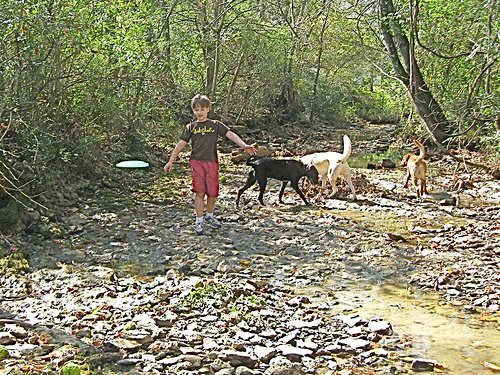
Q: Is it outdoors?
A: Yes, it is outdoors.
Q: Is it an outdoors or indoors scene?
A: It is outdoors.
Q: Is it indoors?
A: No, it is outdoors.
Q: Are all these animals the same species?
A: Yes, all the animals are dogs.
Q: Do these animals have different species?
A: No, all the animals are dogs.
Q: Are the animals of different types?
A: No, all the animals are dogs.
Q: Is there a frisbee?
A: Yes, there is a frisbee.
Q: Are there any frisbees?
A: Yes, there is a frisbee.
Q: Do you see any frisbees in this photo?
A: Yes, there is a frisbee.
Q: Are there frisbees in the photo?
A: Yes, there is a frisbee.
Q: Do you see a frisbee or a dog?
A: Yes, there is a frisbee.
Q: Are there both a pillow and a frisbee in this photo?
A: No, there is a frisbee but no pillows.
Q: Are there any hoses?
A: No, there are no hoses.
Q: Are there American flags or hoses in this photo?
A: No, there are no hoses or American flags.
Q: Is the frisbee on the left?
A: Yes, the frisbee is on the left of the image.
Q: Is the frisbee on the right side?
A: No, the frisbee is on the left of the image.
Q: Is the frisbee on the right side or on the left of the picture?
A: The frisbee is on the left of the image.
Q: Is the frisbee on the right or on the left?
A: The frisbee is on the left of the image.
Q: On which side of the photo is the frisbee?
A: The frisbee is on the left of the image.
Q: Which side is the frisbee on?
A: The frisbee is on the left of the image.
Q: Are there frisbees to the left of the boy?
A: Yes, there is a frisbee to the left of the boy.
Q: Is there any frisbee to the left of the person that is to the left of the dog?
A: Yes, there is a frisbee to the left of the boy.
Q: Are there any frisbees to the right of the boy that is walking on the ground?
A: No, the frisbee is to the left of the boy.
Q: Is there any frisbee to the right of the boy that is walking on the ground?
A: No, the frisbee is to the left of the boy.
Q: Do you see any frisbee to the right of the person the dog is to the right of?
A: No, the frisbee is to the left of the boy.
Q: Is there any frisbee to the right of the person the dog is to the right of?
A: No, the frisbee is to the left of the boy.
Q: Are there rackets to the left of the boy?
A: No, there is a frisbee to the left of the boy.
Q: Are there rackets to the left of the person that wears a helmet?
A: No, there is a frisbee to the left of the boy.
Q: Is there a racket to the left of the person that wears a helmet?
A: No, there is a frisbee to the left of the boy.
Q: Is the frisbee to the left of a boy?
A: Yes, the frisbee is to the left of a boy.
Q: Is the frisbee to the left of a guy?
A: No, the frisbee is to the left of a boy.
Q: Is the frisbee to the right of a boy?
A: No, the frisbee is to the left of a boy.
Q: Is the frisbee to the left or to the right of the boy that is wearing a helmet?
A: The frisbee is to the left of the boy.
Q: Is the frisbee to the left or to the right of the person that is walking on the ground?
A: The frisbee is to the left of the boy.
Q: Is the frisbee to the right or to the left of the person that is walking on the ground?
A: The frisbee is to the left of the boy.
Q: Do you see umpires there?
A: No, there are no umpires.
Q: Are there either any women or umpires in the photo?
A: No, there are no umpires or women.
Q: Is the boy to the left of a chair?
A: No, the boy is to the left of the dog.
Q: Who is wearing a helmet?
A: The boy is wearing a helmet.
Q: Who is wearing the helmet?
A: The boy is wearing a helmet.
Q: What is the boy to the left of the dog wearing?
A: The boy is wearing a helmet.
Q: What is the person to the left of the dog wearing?
A: The boy is wearing a helmet.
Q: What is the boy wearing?
A: The boy is wearing a helmet.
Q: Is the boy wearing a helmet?
A: Yes, the boy is wearing a helmet.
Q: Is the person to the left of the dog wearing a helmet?
A: Yes, the boy is wearing a helmet.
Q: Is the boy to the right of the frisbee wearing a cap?
A: No, the boy is wearing a helmet.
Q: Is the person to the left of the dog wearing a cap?
A: No, the boy is wearing a helmet.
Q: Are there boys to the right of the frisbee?
A: Yes, there is a boy to the right of the frisbee.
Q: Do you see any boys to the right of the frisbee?
A: Yes, there is a boy to the right of the frisbee.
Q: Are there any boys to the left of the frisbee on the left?
A: No, the boy is to the right of the frisbee.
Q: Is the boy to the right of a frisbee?
A: Yes, the boy is to the right of a frisbee.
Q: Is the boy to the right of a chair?
A: No, the boy is to the right of a frisbee.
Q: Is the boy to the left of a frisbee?
A: No, the boy is to the right of a frisbee.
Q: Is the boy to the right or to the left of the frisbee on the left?
A: The boy is to the right of the frisbee.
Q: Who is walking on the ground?
A: The boy is walking on the ground.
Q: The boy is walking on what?
A: The boy is walking on the ground.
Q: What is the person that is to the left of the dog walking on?
A: The boy is walking on the ground.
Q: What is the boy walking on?
A: The boy is walking on the ground.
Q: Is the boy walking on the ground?
A: Yes, the boy is walking on the ground.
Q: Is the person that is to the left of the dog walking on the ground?
A: Yes, the boy is walking on the ground.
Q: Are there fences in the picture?
A: No, there are no fences.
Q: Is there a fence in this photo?
A: No, there are no fences.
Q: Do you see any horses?
A: No, there are no horses.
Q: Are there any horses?
A: No, there are no horses.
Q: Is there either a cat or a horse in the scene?
A: No, there are no horses or cats.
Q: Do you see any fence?
A: No, there are no fences.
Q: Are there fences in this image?
A: No, there are no fences.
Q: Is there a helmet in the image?
A: Yes, there is a helmet.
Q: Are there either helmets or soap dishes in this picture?
A: Yes, there is a helmet.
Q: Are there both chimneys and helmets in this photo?
A: No, there is a helmet but no chimneys.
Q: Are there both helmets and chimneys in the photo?
A: No, there is a helmet but no chimneys.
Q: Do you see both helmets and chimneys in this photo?
A: No, there is a helmet but no chimneys.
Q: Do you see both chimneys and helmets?
A: No, there is a helmet but no chimneys.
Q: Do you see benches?
A: No, there are no benches.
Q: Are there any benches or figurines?
A: No, there are no benches or figurines.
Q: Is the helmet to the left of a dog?
A: Yes, the helmet is to the left of a dog.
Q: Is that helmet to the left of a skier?
A: No, the helmet is to the left of a dog.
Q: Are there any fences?
A: No, there are no fences.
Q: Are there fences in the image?
A: No, there are no fences.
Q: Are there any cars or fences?
A: No, there are no fences or cars.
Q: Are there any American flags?
A: No, there are no American flags.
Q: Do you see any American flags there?
A: No, there are no American flags.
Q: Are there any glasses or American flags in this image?
A: No, there are no American flags or glasses.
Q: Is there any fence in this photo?
A: No, there are no fences.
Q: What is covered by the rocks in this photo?
A: The ground is covered by the rocks.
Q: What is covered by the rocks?
A: The ground is covered by the rocks.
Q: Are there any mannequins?
A: No, there are no mannequins.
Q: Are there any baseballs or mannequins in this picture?
A: No, there are no mannequins or baseballs.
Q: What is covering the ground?
A: The rocks are covering the ground.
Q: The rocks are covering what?
A: The rocks are covering the ground.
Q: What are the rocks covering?
A: The rocks are covering the ground.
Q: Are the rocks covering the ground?
A: Yes, the rocks are covering the ground.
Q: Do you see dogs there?
A: Yes, there is a dog.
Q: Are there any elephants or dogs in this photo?
A: Yes, there is a dog.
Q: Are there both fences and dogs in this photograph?
A: No, there is a dog but no fences.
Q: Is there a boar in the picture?
A: No, there are no boars.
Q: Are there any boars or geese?
A: No, there are no boars or geese.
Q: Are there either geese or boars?
A: No, there are no boars or geese.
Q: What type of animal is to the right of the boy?
A: The animal is a dog.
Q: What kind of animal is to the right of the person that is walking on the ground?
A: The animal is a dog.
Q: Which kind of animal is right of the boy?
A: The animal is a dog.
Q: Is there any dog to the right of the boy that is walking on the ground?
A: Yes, there is a dog to the right of the boy.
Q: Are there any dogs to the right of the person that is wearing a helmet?
A: Yes, there is a dog to the right of the boy.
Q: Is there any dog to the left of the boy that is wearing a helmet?
A: No, the dog is to the right of the boy.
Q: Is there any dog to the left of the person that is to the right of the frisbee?
A: No, the dog is to the right of the boy.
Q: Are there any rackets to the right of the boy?
A: No, there is a dog to the right of the boy.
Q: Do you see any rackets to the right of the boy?
A: No, there is a dog to the right of the boy.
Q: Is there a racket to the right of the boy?
A: No, there is a dog to the right of the boy.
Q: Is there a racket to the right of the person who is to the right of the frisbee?
A: No, there is a dog to the right of the boy.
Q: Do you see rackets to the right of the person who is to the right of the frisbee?
A: No, there is a dog to the right of the boy.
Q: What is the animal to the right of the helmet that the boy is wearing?
A: The animal is a dog.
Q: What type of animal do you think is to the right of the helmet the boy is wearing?
A: The animal is a dog.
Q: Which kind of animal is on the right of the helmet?
A: The animal is a dog.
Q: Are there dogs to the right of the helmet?
A: Yes, there is a dog to the right of the helmet.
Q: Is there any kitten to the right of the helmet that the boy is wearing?
A: No, there is a dog to the right of the helmet.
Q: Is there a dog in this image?
A: Yes, there is a dog.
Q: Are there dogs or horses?
A: Yes, there is a dog.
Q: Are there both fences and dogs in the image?
A: No, there is a dog but no fences.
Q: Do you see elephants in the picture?
A: No, there are no elephants.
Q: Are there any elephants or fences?
A: No, there are no elephants or fences.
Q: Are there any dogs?
A: Yes, there is a dog.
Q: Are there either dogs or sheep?
A: Yes, there is a dog.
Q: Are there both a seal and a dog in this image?
A: No, there is a dog but no seals.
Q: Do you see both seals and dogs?
A: No, there is a dog but no seals.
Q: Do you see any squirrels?
A: No, there are no squirrels.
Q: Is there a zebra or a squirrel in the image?
A: No, there are no squirrels or zebras.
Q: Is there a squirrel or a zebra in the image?
A: No, there are no squirrels or zebras.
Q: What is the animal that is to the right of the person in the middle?
A: The animal is a dog.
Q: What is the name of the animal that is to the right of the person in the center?
A: The animal is a dog.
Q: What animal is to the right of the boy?
A: The animal is a dog.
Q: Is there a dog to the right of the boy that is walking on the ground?
A: Yes, there is a dog to the right of the boy.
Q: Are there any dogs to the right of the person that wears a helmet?
A: Yes, there is a dog to the right of the boy.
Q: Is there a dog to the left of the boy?
A: No, the dog is to the right of the boy.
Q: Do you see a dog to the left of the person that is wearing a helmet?
A: No, the dog is to the right of the boy.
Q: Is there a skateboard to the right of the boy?
A: No, there is a dog to the right of the boy.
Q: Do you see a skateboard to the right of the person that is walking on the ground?
A: No, there is a dog to the right of the boy.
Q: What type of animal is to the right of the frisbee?
A: The animal is a dog.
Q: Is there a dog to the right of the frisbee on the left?
A: Yes, there is a dog to the right of the frisbee.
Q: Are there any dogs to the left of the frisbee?
A: No, the dog is to the right of the frisbee.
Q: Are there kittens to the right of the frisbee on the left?
A: No, there is a dog to the right of the frisbee.